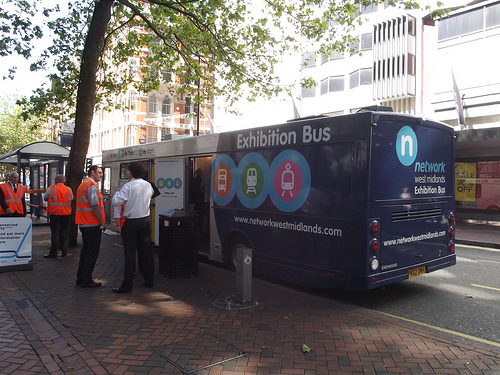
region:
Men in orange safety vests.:
[2, 166, 111, 295]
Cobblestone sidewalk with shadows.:
[35, 276, 357, 372]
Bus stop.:
[5, 139, 77, 241]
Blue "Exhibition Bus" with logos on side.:
[107, 112, 460, 295]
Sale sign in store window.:
[457, 129, 497, 231]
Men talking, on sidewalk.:
[76, 155, 161, 316]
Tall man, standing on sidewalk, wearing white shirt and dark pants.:
[113, 157, 178, 332]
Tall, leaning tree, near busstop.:
[6, 7, 228, 257]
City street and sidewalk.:
[5, 6, 492, 371]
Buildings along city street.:
[76, 0, 497, 234]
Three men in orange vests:
[0, 164, 105, 287]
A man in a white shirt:
[110, 157, 155, 292]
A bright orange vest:
[72, 175, 105, 225]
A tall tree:
[1, 0, 452, 250]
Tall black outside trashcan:
[155, 207, 202, 279]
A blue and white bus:
[100, 102, 457, 289]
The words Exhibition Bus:
[232, 124, 335, 149]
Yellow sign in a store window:
[455, 161, 476, 202]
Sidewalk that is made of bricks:
[0, 221, 497, 373]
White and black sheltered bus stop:
[1, 139, 72, 225]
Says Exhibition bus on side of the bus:
[234, 123, 334, 149]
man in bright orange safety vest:
[72, 164, 110, 287]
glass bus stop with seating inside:
[0, 141, 78, 227]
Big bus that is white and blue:
[106, 103, 458, 295]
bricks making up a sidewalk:
[269, 305, 365, 374]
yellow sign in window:
[453, 163, 480, 203]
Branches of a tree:
[117, 3, 256, 80]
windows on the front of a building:
[288, 39, 373, 104]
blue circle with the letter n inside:
[396, 124, 418, 166]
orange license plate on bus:
[406, 265, 427, 278]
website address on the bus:
[227, 212, 352, 238]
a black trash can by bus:
[155, 207, 204, 279]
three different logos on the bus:
[212, 152, 319, 208]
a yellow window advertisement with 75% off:
[455, 157, 480, 210]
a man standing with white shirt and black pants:
[112, 165, 160, 293]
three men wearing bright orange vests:
[1, 162, 116, 225]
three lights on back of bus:
[370, 222, 383, 277]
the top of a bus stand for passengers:
[0, 140, 71, 162]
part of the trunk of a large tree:
[67, 0, 109, 157]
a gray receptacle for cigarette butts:
[212, 239, 262, 312]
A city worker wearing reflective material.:
[64, 163, 107, 290]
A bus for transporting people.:
[88, 103, 459, 267]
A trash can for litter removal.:
[153, 200, 204, 282]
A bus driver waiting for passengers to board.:
[109, 157, 158, 294]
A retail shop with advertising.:
[447, 157, 498, 232]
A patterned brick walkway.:
[58, 267, 270, 357]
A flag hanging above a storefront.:
[434, 72, 474, 119]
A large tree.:
[27, 19, 206, 244]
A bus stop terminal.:
[11, 139, 72, 224]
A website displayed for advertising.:
[223, 213, 350, 239]